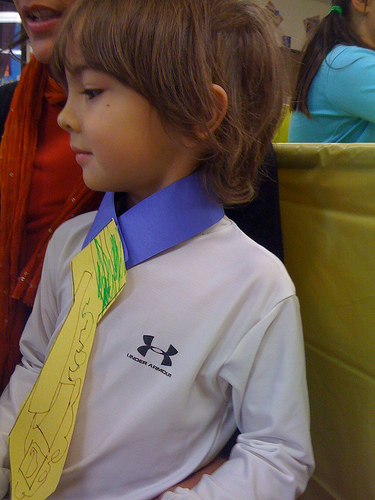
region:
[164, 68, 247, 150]
ear of the kid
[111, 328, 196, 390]
logo on the shirt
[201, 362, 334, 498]
arm of the kid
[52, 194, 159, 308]
fake tie on kid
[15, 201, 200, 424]
yellow and blue piece of paper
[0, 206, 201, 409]
paper shaped like a tie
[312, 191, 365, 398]
lines on the wall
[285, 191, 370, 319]
wall behind the kid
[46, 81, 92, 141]
nose of the kid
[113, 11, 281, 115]
hair on the kid's head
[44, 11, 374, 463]
Little boy with a white shirt.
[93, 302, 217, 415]
Logo on the white shirt.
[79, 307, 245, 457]
Under Armour logo.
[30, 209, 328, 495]
Fake tie on the boy.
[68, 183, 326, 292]
Collar on the shirt.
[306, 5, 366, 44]
Green pony tail holder.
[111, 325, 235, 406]
Dark logo on the shirt.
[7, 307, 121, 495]
Yellow paper tie on the shirt.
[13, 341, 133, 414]
Drawing on the tie.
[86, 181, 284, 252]
Blue paper collar.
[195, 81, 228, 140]
Left ear of a boy in a blue collar.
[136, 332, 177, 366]
A black under armour symbol.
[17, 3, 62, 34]
Lips of a woman behind a boy.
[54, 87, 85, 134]
Small curled up nose on a boy's face.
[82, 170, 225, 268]
A blue collar around a boys neck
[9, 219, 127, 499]
A yellow tie made of paper around a boys neck.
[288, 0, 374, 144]
A girl with dark hair in a blue shirt.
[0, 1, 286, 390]
A woman behind a boy with her mouth open.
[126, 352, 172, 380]
The word Under Armour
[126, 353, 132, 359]
The black U in UNDER.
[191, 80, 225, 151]
the boy's left ear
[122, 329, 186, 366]
under armour logo on shirt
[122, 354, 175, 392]
under armour name on shirt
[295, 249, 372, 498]
yellow painted wall behind boy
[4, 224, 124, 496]
yellow paper tie on boy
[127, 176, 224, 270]
the boy's blue collar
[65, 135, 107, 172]
the little boy's lips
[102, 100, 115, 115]
mole on the boys face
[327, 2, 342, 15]
green band in girl's hair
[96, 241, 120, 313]
green coloring on tie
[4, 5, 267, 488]
child with a woman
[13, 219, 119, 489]
paper cut out tie on child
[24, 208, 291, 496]
shirt on the child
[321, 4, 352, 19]
tie in woman's hair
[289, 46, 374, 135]
shirt on a woman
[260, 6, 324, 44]
images on the wall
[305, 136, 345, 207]
back of a seat